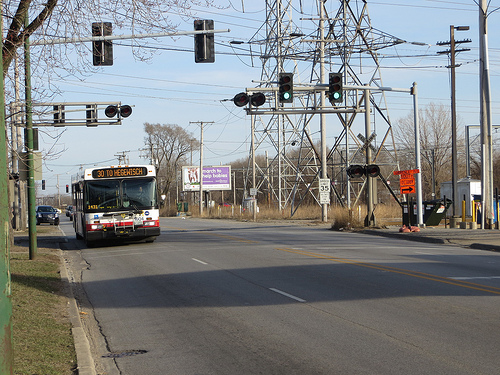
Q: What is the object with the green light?
A: A traffic light.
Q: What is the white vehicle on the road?
A: A bus.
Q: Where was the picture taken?
A: On a street.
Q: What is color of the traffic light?
A: Green.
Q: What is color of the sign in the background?
A: Purple and white.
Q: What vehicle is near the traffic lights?
A: A bus.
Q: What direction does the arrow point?
A: To the right.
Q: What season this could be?
A: Autumn.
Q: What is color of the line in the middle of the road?
A: Yellow.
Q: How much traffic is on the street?
A: Very little.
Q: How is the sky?
A: Cloudy.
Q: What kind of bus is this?
A: City transit bus.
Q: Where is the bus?
A: On the highway.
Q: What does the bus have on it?
A: 30 TO HEGEWISCH.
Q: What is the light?
A: Green light.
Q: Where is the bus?
A: An intersection.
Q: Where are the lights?
A: On poles.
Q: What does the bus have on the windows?
A: Wipers.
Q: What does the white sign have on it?
A: 35.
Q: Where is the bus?
A: Near the railroad tracks.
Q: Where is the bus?
A: On the street.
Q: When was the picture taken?
A: Daytime.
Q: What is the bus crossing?
A: Railroad tracks.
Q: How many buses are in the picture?
A: One.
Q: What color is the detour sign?
A: Orange.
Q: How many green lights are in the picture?
A: Two.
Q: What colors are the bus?
A: Red and white.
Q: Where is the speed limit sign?
A: On a pole.